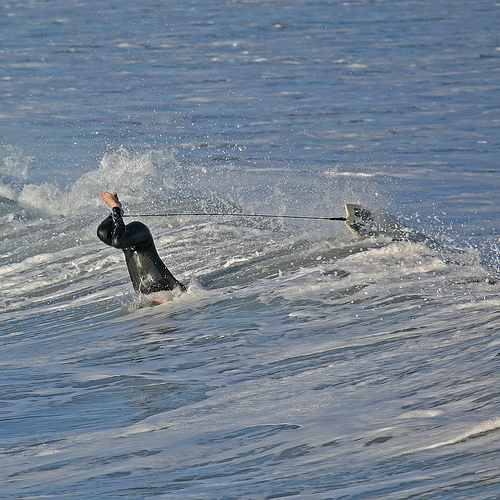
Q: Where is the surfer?
A: Underwater.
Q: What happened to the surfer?
A: He fell.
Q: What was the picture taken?
A: Daytime.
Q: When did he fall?
A: Just now.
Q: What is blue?
A: Water.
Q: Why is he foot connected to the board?
A: So he doesn't lose the board.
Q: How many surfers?
A: One.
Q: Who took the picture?
A: Man.